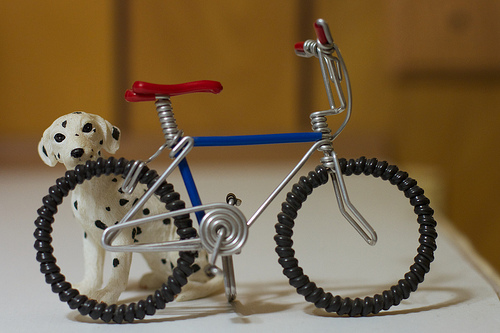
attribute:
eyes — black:
[51, 120, 95, 144]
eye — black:
[82, 119, 95, 134]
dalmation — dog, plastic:
[30, 86, 215, 321]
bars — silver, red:
[296, 21, 338, 79]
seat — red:
[121, 70, 228, 107]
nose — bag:
[63, 141, 93, 168]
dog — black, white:
[35, 110, 225, 321]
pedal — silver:
[192, 257, 232, 282]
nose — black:
[68, 147, 87, 158]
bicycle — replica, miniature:
[27, 18, 443, 325]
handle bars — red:
[289, 14, 344, 68]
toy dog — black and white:
[37, 107, 234, 314]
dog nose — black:
[67, 146, 88, 162]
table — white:
[17, 160, 494, 327]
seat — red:
[122, 76, 227, 108]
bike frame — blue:
[29, 13, 443, 325]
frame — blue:
[96, 110, 385, 253]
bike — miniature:
[33, 10, 443, 324]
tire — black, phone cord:
[274, 152, 439, 317]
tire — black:
[32, 154, 203, 324]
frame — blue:
[98, 112, 377, 262]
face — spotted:
[25, 105, 130, 167]